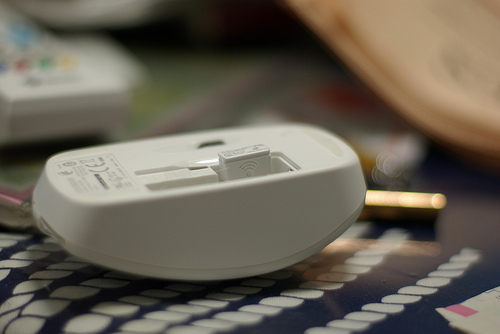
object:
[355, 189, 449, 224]
object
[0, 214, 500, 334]
cloth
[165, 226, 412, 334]
design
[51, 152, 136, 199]
label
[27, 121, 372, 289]
mouse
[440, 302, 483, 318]
rectangle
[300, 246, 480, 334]
design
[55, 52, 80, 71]
button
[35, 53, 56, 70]
button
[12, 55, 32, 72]
button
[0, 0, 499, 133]
background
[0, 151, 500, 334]
foreground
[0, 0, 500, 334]
table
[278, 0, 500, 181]
cloth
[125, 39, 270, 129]
cloth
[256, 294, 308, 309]
polkadot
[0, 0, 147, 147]
phone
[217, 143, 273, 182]
wifi symbol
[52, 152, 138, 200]
text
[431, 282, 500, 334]
paper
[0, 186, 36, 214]
object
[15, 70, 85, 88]
icon